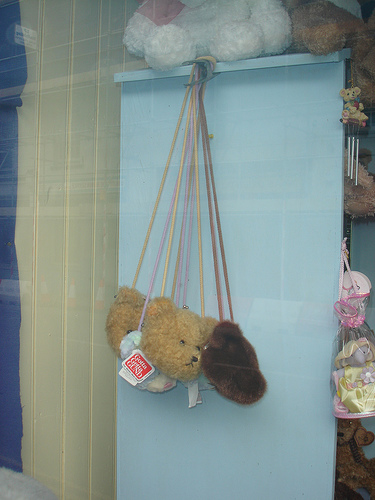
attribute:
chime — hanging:
[345, 135, 350, 177]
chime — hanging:
[350, 133, 355, 180]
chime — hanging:
[354, 137, 359, 184]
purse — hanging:
[201, 320, 266, 406]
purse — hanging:
[144, 295, 216, 381]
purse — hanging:
[119, 330, 181, 392]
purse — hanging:
[106, 284, 153, 359]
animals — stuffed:
[122, 1, 373, 66]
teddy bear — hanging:
[96, 288, 224, 392]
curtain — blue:
[0, 0, 27, 475]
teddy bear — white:
[122, 0, 291, 69]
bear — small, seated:
[338, 84, 369, 119]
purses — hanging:
[87, 46, 272, 408]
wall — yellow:
[25, 100, 119, 203]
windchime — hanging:
[99, 53, 268, 406]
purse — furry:
[111, 288, 266, 407]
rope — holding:
[130, 54, 241, 329]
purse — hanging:
[100, 279, 175, 366]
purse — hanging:
[136, 292, 217, 384]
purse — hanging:
[199, 315, 272, 408]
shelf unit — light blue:
[102, 43, 351, 498]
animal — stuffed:
[313, 299, 374, 430]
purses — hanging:
[112, 69, 265, 401]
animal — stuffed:
[99, 268, 210, 397]